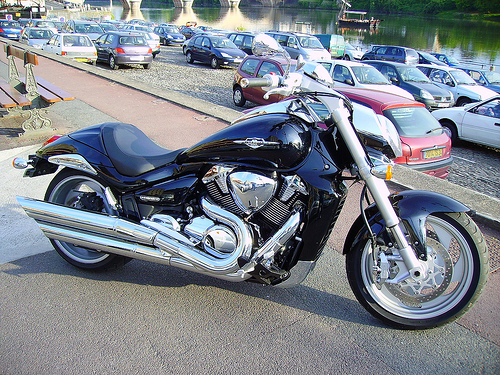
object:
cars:
[0, 17, 499, 181]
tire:
[343, 189, 490, 334]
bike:
[13, 61, 490, 328]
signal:
[40, 134, 64, 148]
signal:
[367, 152, 396, 182]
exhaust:
[13, 188, 204, 273]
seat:
[103, 121, 190, 176]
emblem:
[231, 135, 279, 149]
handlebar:
[239, 69, 296, 101]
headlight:
[368, 162, 395, 179]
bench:
[0, 44, 83, 109]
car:
[323, 89, 451, 185]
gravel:
[154, 56, 203, 84]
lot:
[0, 18, 499, 153]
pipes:
[17, 190, 255, 285]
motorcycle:
[11, 64, 492, 329]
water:
[419, 24, 449, 41]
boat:
[333, 7, 379, 31]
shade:
[310, 177, 348, 280]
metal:
[197, 156, 308, 254]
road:
[93, 84, 139, 118]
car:
[180, 32, 251, 67]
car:
[40, 33, 98, 71]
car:
[87, 30, 154, 69]